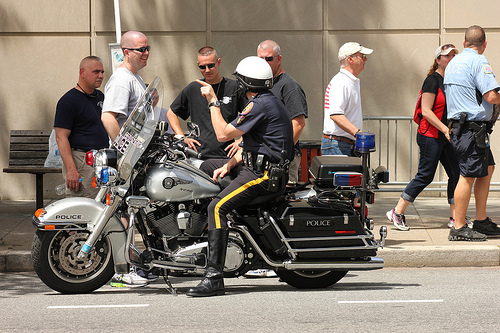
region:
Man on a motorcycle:
[192, 62, 299, 319]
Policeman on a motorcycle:
[191, 54, 298, 298]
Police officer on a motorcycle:
[185, 52, 306, 299]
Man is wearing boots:
[185, 220, 230, 295]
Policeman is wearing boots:
[188, 224, 235, 299]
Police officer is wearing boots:
[185, 225, 237, 297]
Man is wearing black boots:
[185, 225, 238, 296]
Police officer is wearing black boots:
[178, 226, 233, 296]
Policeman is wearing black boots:
[189, 222, 235, 297]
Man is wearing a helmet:
[229, 52, 277, 92]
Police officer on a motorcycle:
[47, 47, 388, 287]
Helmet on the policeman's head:
[225, 55, 277, 95]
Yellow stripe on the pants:
[212, 165, 275, 236]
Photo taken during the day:
[16, 13, 498, 320]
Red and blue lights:
[77, 150, 115, 182]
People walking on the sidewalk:
[318, 20, 493, 237]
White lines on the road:
[27, 295, 449, 307]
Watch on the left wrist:
[205, 100, 225, 107]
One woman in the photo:
[389, 48, 460, 238]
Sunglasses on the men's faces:
[130, 44, 285, 66]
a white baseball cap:
[335, 36, 375, 63]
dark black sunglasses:
[124, 45, 150, 54]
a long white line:
[337, 293, 444, 305]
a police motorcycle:
[28, 75, 392, 300]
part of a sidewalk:
[363, 190, 498, 248]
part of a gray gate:
[362, 113, 433, 189]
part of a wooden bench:
[4, 128, 70, 200]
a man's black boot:
[183, 222, 229, 297]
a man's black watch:
[207, 99, 224, 108]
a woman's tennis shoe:
[386, 208, 413, 231]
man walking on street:
[317, 41, 369, 155]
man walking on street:
[441, 31, 496, 240]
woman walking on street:
[384, 37, 458, 233]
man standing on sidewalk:
[247, 37, 302, 184]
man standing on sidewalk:
[167, 43, 241, 156]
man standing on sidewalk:
[100, 31, 155, 146]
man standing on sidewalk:
[50, 54, 110, 205]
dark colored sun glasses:
[121, 44, 151, 54]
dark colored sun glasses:
[197, 61, 219, 72]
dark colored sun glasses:
[255, 52, 279, 63]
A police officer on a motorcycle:
[184, 53, 294, 297]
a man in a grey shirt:
[100, 28, 157, 148]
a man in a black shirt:
[260, 40, 309, 144]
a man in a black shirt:
[166, 44, 248, 159]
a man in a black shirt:
[51, 53, 111, 199]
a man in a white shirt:
[318, 38, 370, 157]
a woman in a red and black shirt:
[383, 42, 453, 232]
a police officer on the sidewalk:
[438, 23, 499, 243]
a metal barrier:
[363, 109, 498, 198]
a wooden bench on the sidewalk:
[1, 127, 63, 209]